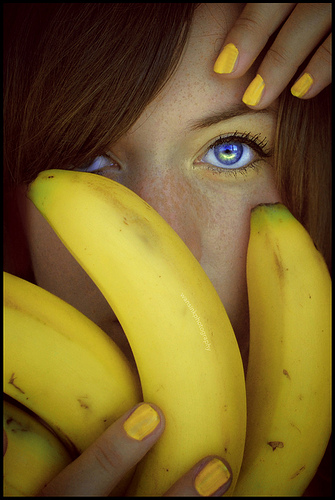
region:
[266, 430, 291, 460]
small spot on the banana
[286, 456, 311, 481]
small line on the banana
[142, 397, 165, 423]
edge of girl's fingernail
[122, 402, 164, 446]
yellow paint on the nail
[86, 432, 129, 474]
grooves in the girl's finger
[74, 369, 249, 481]
girl's finger on the banana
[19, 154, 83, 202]
green tip of the banana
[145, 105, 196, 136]
freckles on girl's face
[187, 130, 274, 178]
yellow reflection in girl's eye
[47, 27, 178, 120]
ginger hair on girl's head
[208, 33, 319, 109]
Yellow fingernail polish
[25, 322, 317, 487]
A hand holding up yellow bananas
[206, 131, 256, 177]
Blue eyes shining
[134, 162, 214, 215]
A freckled nose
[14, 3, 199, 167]
Auburn hair slanting across a forehead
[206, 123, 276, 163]
Dark mascara coated eyelashes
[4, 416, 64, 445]
A bruise on a banana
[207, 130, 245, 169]
Light reflecting in an eye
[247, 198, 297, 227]
The green end of a banana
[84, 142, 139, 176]
An eye with only the white visible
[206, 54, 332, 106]
yellow painted women's nails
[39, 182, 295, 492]
4 bunches of banana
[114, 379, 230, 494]
two fingers painted in yellow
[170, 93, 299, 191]
yellow eye shadow on eyes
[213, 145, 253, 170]
blue and yellow colored eyes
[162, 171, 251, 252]
freckles on nose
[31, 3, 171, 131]
red hair shaped bangs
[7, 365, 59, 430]
bruises on bananas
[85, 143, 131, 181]
corner of eyeball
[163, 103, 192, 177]
fair skin with freckles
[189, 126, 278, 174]
the eye of a girl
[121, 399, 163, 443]
a yellow finger nail of the girl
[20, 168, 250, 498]
a yellow banana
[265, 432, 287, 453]
a brown spot on the banana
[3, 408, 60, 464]
a green streak in the banana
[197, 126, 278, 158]
the eye lashes of the girl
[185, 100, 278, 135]
the eyebrow of the girl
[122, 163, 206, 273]
the nose of the girl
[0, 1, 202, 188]
the red hair of the girl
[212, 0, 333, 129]
the fingers of the girl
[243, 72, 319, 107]
fingernails painted yellow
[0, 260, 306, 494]
a bunch of bananas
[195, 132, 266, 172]
a womans blue eye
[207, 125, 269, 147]
mascara coated eyelashes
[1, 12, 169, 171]
auburn colored hair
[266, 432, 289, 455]
a brown spot on a banana peel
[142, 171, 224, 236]
freckles on a womans face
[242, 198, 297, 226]
the green tip of a banana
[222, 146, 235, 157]
the black pupil of an eye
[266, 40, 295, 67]
the wrinkles of a finger